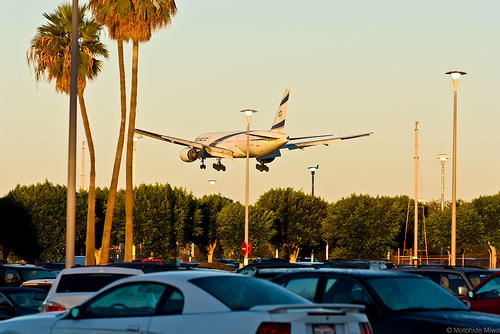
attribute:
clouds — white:
[2, 68, 499, 204]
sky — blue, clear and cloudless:
[1, 0, 498, 205]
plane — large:
[122, 82, 379, 177]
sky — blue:
[184, 2, 498, 100]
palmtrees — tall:
[25, 3, 180, 293]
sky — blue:
[222, 19, 420, 106]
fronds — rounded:
[50, 0, 180, 135]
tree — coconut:
[24, 26, 162, 191]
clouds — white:
[0, 0, 499, 205]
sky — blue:
[181, 7, 405, 79]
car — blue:
[246, 250, 446, 332]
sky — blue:
[182, 3, 441, 85]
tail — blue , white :
[270, 78, 297, 142]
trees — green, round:
[0, 180, 499, 265]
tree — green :
[217, 201, 274, 259]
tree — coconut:
[87, 1, 178, 263]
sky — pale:
[208, 45, 320, 77]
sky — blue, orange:
[220, 1, 411, 58]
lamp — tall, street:
[421, 66, 471, 253]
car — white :
[34, 260, 156, 322]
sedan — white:
[0, 268, 372, 331]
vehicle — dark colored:
[273, 262, 498, 332]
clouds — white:
[301, 40, 383, 89]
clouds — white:
[332, 33, 434, 113]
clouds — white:
[15, 3, 497, 232]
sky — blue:
[38, 22, 479, 209]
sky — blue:
[152, 44, 490, 202]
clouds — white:
[365, 26, 448, 106]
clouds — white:
[335, 153, 416, 193]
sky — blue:
[182, 22, 483, 165]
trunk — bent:
[82, 111, 101, 242]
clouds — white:
[371, 94, 488, 184]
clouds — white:
[305, 30, 493, 175]